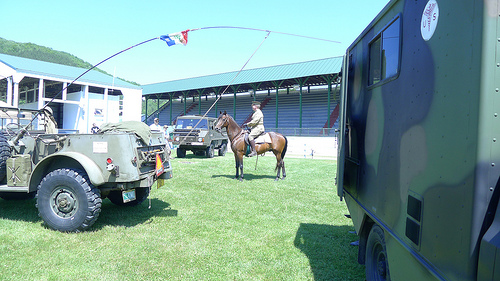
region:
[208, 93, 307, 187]
Military horse with rider.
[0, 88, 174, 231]
Military jeep for transportation of small troops.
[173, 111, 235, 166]
Troop carrier for moving larger equipment and troops.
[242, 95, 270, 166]
Calvary serviceman on top of his horse.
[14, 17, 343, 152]
Communications antennae with nations flag.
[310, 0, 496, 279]
Military truck in camouflage.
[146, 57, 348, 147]
Parade grandstands for spectators.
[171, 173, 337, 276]
Grass field.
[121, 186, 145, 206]
Vehicle license plate.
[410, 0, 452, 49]
U.S. symbol on the side of the ambulance.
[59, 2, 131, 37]
this is the sky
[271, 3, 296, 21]
the sky is blue in color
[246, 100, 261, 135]
this is a soldier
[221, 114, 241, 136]
this is a horse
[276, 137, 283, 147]
the horse is brown in color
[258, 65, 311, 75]
this is a roof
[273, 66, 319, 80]
the roof is blue in color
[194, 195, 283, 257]
this is a grass area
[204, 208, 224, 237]
the grass is green in color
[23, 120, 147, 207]
this is a vehicle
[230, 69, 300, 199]
The person is on the horse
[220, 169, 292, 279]
The grass is green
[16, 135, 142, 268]
The vehicle has large tires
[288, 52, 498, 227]
This vehicle is camo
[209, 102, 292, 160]
The horse is brown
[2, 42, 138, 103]
The building has a green roof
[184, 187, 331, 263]
The sun is shining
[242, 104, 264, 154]
The woman has a jacket on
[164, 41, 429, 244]
No one is in the stands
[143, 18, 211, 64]
This flag is red, white and blue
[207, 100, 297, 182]
person on a horse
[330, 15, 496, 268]
a vehicle painted in camouflage colors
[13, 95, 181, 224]
a military jeep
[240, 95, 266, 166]
a person in a uniform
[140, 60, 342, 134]
empty bleachers with a green roof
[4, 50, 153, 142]
a white building with a green roof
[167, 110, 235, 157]
a dark green military vehicle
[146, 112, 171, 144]
people in the distance wearing hats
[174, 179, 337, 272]
bright green, shortly mowed grass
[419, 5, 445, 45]
U.S. Army medical insignia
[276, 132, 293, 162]
horse tail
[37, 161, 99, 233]
a black jeep tire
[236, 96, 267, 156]
a person riding a horse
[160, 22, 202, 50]
a flag on a pole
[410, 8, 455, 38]
a sticker on a vehicle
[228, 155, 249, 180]
a horses two front legs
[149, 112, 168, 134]
a person next to a vehicle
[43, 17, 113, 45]
the blue and aqua sky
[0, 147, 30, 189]
a gas can in a jeep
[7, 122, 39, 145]
a steering wheel in a jeep